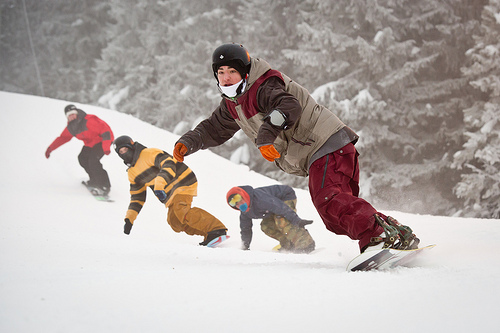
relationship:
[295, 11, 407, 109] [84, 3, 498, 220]
snow on trees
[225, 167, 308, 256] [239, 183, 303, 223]
man wearing coat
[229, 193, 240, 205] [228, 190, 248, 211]
goggle on face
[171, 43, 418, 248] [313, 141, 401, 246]
boy wearing pants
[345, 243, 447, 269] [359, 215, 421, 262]
snowboard on man's feet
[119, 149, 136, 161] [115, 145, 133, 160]
mask covering face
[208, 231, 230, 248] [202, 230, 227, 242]
snowboard under foot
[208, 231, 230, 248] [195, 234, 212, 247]
snowboard under foot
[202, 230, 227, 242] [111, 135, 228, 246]
foot of boy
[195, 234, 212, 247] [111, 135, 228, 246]
foot of boy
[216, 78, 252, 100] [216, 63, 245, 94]
scarf around face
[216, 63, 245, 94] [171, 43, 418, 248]
face of boy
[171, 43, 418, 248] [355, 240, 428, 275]
boy on snowboards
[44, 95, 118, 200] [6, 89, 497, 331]
man snowboarding on hill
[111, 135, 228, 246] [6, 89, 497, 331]
boy snowboarding on hill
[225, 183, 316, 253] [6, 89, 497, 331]
man snowboarding on hill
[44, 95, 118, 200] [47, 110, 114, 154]
man wearing coat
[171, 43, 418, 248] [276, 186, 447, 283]
boy tilting sideways on snowboard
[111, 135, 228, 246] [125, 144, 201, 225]
boy wearing coat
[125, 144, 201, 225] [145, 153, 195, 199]
coat with stripes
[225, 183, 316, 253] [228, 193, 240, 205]
man with goggles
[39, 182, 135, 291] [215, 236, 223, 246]
snow board with design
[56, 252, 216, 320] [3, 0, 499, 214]
snow covered trees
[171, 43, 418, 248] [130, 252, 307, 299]
boy down hill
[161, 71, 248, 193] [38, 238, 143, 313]
arm touching snow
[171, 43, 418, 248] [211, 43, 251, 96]
boy has cap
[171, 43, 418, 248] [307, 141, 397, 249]
boy has burgundy pants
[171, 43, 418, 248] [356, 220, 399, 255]
boy has shoe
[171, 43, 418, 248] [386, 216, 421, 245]
boy has shoe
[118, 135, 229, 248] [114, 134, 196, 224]
boy has brown hood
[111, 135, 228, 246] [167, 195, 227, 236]
boy has orange pants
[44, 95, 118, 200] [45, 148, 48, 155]
man wearing glove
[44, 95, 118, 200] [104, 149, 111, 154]
man wearing glove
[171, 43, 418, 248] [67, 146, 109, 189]
boy wearing pants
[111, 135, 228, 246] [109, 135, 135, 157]
boy wearing cap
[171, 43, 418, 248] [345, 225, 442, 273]
boy skiing on snow board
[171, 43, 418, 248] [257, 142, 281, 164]
boy wearing glove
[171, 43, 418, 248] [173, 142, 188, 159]
boy wearing glove